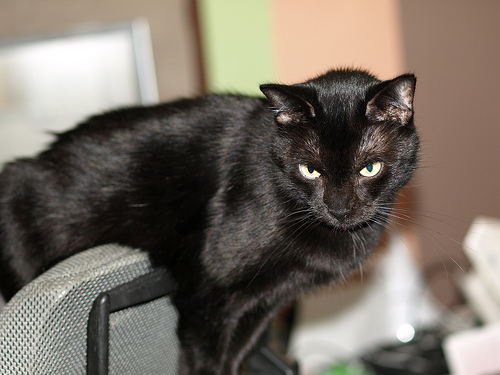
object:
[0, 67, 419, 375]
cat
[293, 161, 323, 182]
green eyes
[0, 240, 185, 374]
grey chair